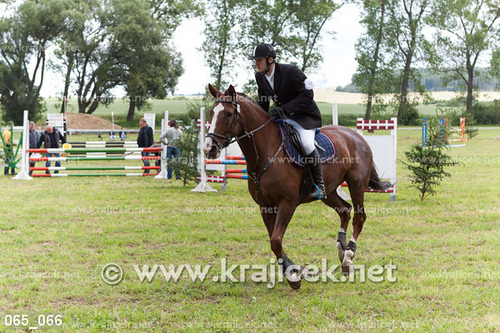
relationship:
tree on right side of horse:
[396, 114, 454, 204] [171, 89, 416, 289]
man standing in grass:
[134, 118, 156, 165] [1, 127, 498, 331]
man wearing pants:
[247, 36, 331, 203] [291, 120, 320, 160]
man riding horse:
[251, 43, 327, 200] [170, 82, 415, 289]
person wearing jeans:
[158, 118, 182, 173] [163, 146, 181, 176]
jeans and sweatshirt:
[163, 146, 181, 176] [157, 126, 182, 148]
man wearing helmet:
[251, 43, 327, 200] [248, 45, 277, 58]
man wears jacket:
[134, 118, 162, 178] [135, 121, 160, 146]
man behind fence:
[134, 118, 162, 178] [12, 107, 215, 179]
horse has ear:
[170, 82, 415, 289] [207, 84, 222, 97]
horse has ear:
[170, 82, 415, 289] [226, 84, 238, 99]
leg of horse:
[319, 187, 352, 262] [170, 82, 415, 289]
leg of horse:
[340, 179, 365, 273] [170, 82, 415, 289]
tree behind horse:
[396, 119, 463, 204] [170, 82, 415, 289]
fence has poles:
[12, 107, 215, 179] [28, 145, 165, 181]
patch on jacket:
[303, 79, 315, 88] [268, 63, 319, 125]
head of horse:
[200, 81, 247, 163] [170, 82, 415, 289]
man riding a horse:
[251, 43, 327, 200] [172, 70, 394, 283]